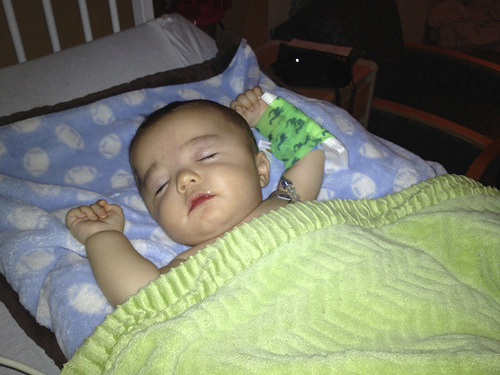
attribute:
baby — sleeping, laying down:
[57, 93, 386, 301]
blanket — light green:
[62, 174, 498, 374]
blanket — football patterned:
[4, 38, 451, 355]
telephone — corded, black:
[286, 49, 362, 109]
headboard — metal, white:
[2, 2, 167, 72]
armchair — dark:
[284, 8, 500, 175]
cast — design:
[258, 90, 350, 170]